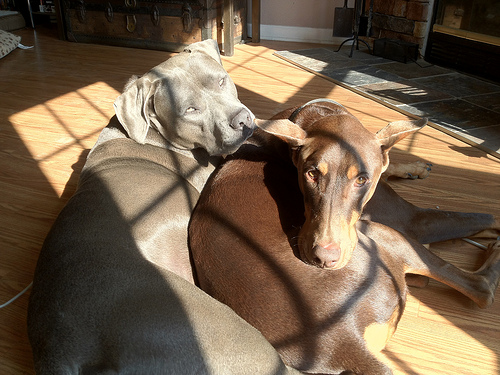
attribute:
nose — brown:
[314, 247, 340, 266]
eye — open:
[183, 103, 196, 112]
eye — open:
[216, 73, 227, 90]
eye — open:
[305, 167, 323, 187]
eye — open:
[350, 173, 372, 191]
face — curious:
[294, 149, 377, 267]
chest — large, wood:
[61, 1, 243, 56]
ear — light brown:
[376, 118, 430, 145]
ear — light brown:
[255, 120, 312, 152]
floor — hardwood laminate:
[6, 56, 99, 146]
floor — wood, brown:
[6, 26, 498, 373]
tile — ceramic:
[350, 45, 492, 175]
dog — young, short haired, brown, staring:
[192, 96, 499, 373]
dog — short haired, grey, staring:
[27, 37, 302, 372]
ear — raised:
[252, 118, 303, 152]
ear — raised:
[375, 118, 426, 152]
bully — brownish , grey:
[24, 33, 280, 373]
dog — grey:
[209, 92, 399, 353]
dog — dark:
[86, 70, 384, 362]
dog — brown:
[192, 69, 468, 374]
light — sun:
[77, 74, 255, 337]